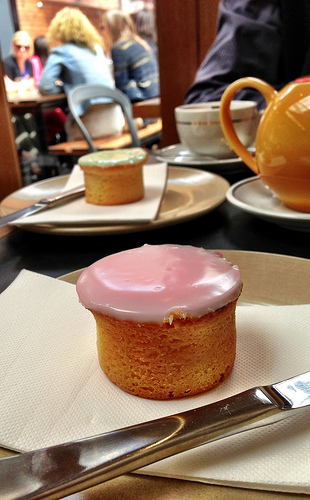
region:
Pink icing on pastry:
[74, 243, 241, 323]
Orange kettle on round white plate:
[214, 70, 308, 211]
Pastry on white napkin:
[75, 243, 243, 402]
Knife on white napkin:
[0, 368, 309, 499]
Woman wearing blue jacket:
[40, 6, 124, 145]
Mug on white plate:
[171, 98, 255, 158]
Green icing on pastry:
[77, 144, 143, 167]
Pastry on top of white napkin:
[75, 148, 147, 205]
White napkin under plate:
[7, 159, 169, 222]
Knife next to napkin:
[0, 179, 85, 248]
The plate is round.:
[0, 142, 232, 242]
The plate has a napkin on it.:
[1, 145, 235, 240]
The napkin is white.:
[1, 134, 231, 242]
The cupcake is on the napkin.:
[1, 141, 238, 247]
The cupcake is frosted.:
[60, 140, 158, 215]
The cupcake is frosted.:
[63, 230, 253, 402]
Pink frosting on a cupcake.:
[61, 237, 260, 406]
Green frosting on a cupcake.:
[66, 143, 155, 209]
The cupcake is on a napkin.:
[0, 241, 309, 495]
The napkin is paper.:
[0, 249, 309, 496]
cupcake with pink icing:
[77, 239, 245, 401]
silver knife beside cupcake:
[9, 384, 304, 497]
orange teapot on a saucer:
[215, 59, 306, 226]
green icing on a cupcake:
[70, 143, 161, 170]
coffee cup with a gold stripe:
[164, 99, 253, 162]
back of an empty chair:
[57, 74, 148, 141]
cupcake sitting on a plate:
[52, 139, 194, 232]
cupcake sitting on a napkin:
[49, 237, 226, 399]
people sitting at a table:
[8, 5, 169, 132]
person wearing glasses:
[10, 35, 35, 65]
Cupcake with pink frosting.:
[75, 240, 247, 404]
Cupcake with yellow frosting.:
[75, 143, 153, 204]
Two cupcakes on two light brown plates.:
[0, 132, 308, 499]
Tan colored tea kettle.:
[217, 65, 309, 208]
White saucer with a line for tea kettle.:
[225, 177, 308, 226]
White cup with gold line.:
[171, 100, 254, 155]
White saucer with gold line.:
[152, 141, 256, 168]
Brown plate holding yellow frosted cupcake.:
[1, 145, 230, 233]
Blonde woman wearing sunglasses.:
[4, 30, 39, 84]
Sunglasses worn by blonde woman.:
[10, 43, 35, 52]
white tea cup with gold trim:
[172, 97, 258, 164]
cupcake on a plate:
[0, 239, 309, 494]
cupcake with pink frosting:
[76, 243, 243, 398]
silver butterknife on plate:
[0, 372, 309, 498]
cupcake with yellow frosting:
[75, 147, 149, 205]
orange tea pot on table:
[217, 64, 308, 215]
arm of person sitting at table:
[175, 1, 308, 105]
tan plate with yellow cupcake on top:
[1, 147, 230, 233]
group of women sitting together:
[1, 0, 160, 131]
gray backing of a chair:
[62, 85, 145, 153]